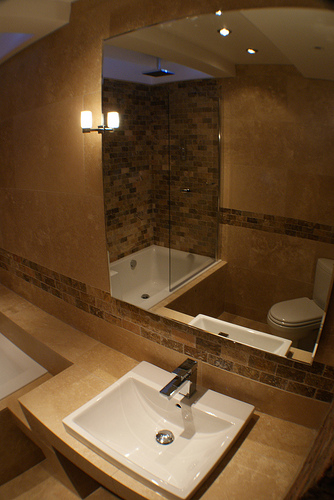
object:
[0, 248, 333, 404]
backsplash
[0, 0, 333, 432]
wall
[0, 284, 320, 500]
counter top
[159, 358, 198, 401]
faucet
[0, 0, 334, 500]
bathroom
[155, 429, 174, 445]
drain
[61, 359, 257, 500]
sink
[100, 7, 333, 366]
mirror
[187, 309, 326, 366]
sink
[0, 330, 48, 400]
bathtub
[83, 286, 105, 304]
tile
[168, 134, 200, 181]
tile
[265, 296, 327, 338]
toilet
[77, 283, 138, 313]
tile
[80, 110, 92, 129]
light